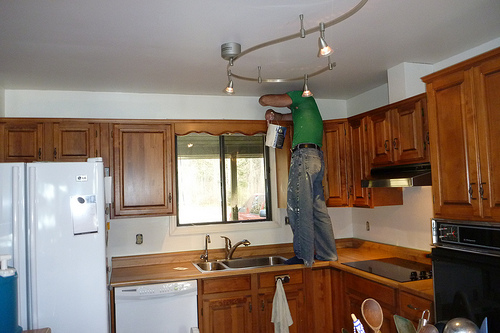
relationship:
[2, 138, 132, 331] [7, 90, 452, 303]
fridge in kitchen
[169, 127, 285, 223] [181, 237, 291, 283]
window over sink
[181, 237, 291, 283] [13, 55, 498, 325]
sink in kitchen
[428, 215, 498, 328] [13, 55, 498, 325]
oven in kitchen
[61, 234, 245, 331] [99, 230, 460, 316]
dishwasher over counter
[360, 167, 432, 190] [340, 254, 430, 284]
hood over stove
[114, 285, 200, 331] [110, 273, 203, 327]
door of dishwasher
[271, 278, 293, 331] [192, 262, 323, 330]
rag hanging from cabinet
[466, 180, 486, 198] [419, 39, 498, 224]
knobs on cabinet doors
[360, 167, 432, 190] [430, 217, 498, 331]
hood over stove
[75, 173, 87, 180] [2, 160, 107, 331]
logo on fridge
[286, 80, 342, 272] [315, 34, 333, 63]
he installing light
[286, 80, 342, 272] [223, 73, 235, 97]
he installing light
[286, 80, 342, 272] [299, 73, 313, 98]
he installing light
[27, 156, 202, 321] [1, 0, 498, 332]
white appliances in kitchen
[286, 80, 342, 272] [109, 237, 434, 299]
he standing on counter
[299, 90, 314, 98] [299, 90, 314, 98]
bulb with bulb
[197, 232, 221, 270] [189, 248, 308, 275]
hose for sink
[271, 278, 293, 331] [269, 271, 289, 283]
rag on handle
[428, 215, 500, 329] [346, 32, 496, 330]
oven installed in wall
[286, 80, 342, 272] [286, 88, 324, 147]
he in shirt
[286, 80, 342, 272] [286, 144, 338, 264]
he in jeans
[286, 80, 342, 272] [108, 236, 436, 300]
he standing on counter top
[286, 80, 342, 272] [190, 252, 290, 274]
he standing by sink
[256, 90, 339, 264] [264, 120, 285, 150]
man can holding can